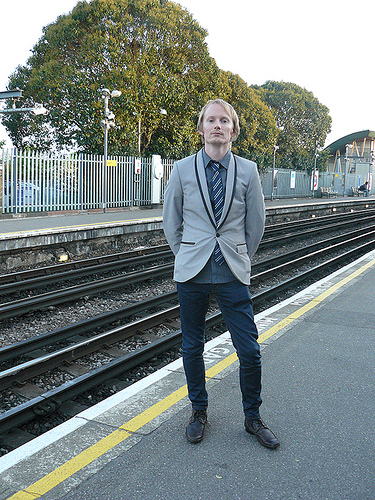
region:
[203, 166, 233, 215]
tie on the man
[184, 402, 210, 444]
shoe on the man's foot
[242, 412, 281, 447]
shoe on the man's foot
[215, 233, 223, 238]
button on the jacket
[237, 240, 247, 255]
pocket on the jacket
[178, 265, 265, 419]
pants on the man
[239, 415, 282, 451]
black shoe on the man's foot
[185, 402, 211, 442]
black shoe on man's foot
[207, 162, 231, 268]
blue and gray tie on the man's foot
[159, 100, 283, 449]
man standing near train tracks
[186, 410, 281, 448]
A pair of brown shoes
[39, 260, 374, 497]
A paved road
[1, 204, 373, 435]
Empty railroads tracks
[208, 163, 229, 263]
A blue striped tie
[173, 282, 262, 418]
A pair of blue pants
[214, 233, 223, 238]
A small black button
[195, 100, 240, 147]
A man with blonde hair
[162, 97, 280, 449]
A man standing by railroad tracks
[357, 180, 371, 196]
A person sitting on a bench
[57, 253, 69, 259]
A yellow light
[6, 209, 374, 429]
two sets of train tracks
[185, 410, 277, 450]
black leather shoes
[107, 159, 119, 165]
yellow sign on the fence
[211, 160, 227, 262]
a blue striped neck tie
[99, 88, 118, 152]
a street light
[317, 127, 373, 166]
a building in the distance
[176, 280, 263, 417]
the blue jeans are skinny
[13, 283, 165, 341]
gravel in between the tracks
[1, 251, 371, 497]
a concrete walk way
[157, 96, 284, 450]
Man in dress jacket and tie standing in front of railroad tracks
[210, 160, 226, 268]
Blue and white striped tie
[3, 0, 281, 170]
Large leafy green tree in background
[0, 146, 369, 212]
Tall fence made of palings running along sidewalk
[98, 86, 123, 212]
Pair of floodlights on post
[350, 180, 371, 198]
Person sitting on bench in background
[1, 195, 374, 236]
Paved walkway alongside railroad tracks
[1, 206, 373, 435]
Multiple sets of railroad tracks in channel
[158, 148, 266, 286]
Gray dinner jacket with black trim on lapels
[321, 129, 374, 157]
Green roof of building in background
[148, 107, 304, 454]
man standing in front of train tracks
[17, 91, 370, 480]
photograph taken on a train platform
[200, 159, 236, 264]
diagonally striped tie around man's neck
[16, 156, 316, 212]
picket fence along train platform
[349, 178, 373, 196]
person sitting on a bench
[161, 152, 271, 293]
man wearing a grey blazer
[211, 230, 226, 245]
black button on blazer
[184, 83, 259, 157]
man with blonde hair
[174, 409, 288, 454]
man wearing brown dress shoes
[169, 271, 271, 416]
man wearing skinny blue jeans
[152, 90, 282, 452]
A man standing on a train platform.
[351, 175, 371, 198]
A person in the background sits on a bench.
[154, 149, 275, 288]
The man is wearing a grey suit jacket.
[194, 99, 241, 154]
the head of a man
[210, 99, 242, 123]
the hair of a man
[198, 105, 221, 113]
the forehead of a man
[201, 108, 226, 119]
the eyebrows of a man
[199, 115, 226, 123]
the eyes of a man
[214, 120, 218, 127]
the nose of a man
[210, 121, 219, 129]
the nostrils of a man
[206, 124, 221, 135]
the mouth of a man